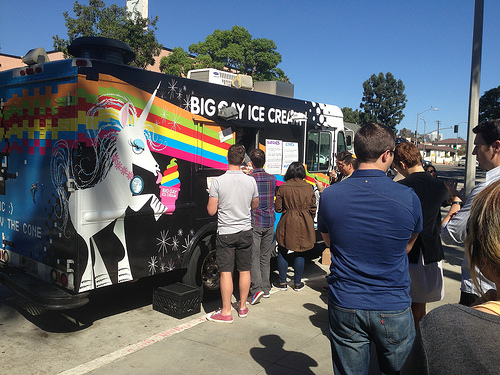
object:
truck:
[0, 36, 355, 316]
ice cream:
[247, 105, 306, 124]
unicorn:
[68, 80, 168, 293]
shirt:
[318, 169, 423, 310]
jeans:
[327, 301, 416, 374]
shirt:
[209, 169, 260, 235]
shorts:
[216, 229, 254, 272]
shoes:
[206, 312, 235, 323]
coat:
[275, 178, 317, 252]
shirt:
[252, 170, 277, 229]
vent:
[68, 35, 136, 65]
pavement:
[0, 243, 465, 375]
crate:
[151, 282, 203, 320]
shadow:
[249, 302, 331, 373]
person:
[274, 161, 318, 292]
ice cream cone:
[159, 157, 182, 216]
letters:
[191, 96, 308, 126]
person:
[316, 124, 424, 374]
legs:
[217, 241, 235, 313]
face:
[342, 163, 350, 175]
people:
[207, 144, 259, 324]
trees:
[50, 0, 289, 81]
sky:
[6, 0, 500, 84]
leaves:
[213, 44, 256, 68]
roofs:
[414, 136, 470, 154]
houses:
[433, 137, 468, 164]